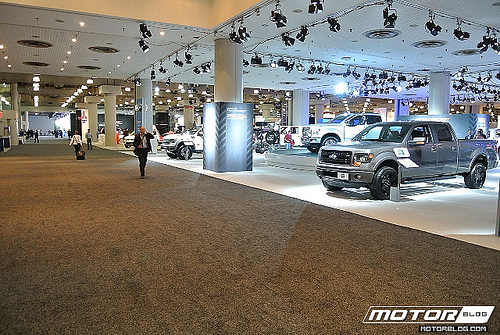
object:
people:
[33, 130, 43, 142]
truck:
[300, 110, 386, 155]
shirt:
[68, 134, 87, 145]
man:
[131, 123, 154, 179]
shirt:
[140, 134, 148, 147]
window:
[406, 123, 435, 146]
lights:
[191, 67, 202, 78]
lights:
[169, 51, 185, 71]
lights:
[165, 77, 175, 89]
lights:
[450, 17, 472, 46]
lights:
[131, 38, 152, 56]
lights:
[247, 51, 264, 71]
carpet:
[0, 124, 499, 334]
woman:
[68, 130, 88, 159]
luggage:
[71, 145, 89, 160]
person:
[283, 127, 295, 151]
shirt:
[284, 134, 293, 143]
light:
[270, 0, 290, 30]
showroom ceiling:
[204, 1, 499, 106]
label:
[386, 144, 424, 176]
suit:
[129, 133, 159, 177]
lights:
[322, 14, 347, 36]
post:
[199, 35, 253, 174]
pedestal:
[252, 144, 383, 207]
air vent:
[12, 37, 53, 51]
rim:
[369, 164, 403, 200]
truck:
[306, 114, 499, 203]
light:
[135, 19, 155, 41]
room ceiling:
[79, 15, 197, 65]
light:
[237, 14, 253, 44]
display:
[391, 143, 420, 172]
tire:
[367, 162, 397, 200]